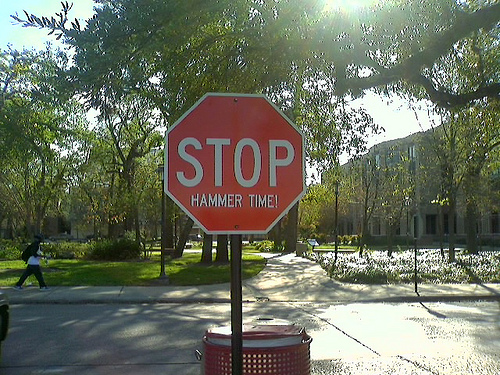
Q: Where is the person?
A: On sidewalk.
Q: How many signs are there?
A: One.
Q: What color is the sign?
A: Red.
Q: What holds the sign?
A: A pole.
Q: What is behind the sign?
A: A trash bin.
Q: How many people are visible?
A: One.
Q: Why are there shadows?
A: It is sunny.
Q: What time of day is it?
A: Morning.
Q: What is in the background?
A: A building.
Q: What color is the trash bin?
A: Red.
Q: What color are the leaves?
A: Green.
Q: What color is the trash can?
A: Red.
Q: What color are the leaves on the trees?
A: Green.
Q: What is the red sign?
A: Stop.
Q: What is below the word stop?
A: Hammer time.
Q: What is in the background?
A: Trees.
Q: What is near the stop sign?
A: Trashcan.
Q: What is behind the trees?
A: Building.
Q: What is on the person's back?
A: Bookbag.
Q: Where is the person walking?
A: Sidewalk.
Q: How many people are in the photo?
A: 1.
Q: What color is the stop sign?
A: Red.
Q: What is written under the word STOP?
A: Hammer Time.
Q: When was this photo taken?
A: Daytime.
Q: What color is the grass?
A: Green.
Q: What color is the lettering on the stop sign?
A: White.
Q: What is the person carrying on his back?
A: Bookbag.